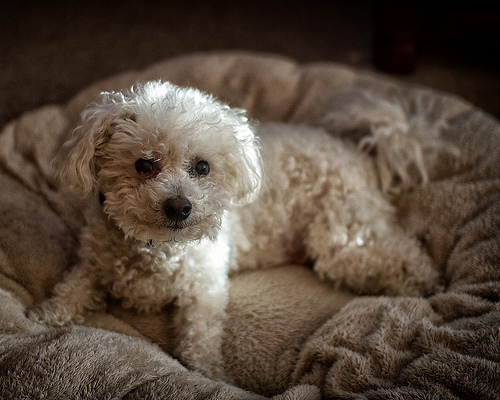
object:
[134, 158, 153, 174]
dark eyes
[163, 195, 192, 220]
nose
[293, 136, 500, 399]
folds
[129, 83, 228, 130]
fur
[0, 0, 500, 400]
ground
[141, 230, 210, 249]
small beard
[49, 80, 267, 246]
head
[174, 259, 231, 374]
leg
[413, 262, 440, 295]
paw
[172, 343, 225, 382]
paw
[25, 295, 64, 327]
paw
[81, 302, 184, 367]
dark seam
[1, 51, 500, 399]
pillow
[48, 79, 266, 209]
curly hair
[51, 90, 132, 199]
ear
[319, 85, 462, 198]
tail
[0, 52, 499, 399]
surface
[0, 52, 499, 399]
bed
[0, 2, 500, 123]
dark background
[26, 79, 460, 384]
dog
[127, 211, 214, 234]
mouth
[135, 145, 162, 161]
fur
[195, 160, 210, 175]
eye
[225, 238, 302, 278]
belly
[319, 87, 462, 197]
direction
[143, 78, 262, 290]
light